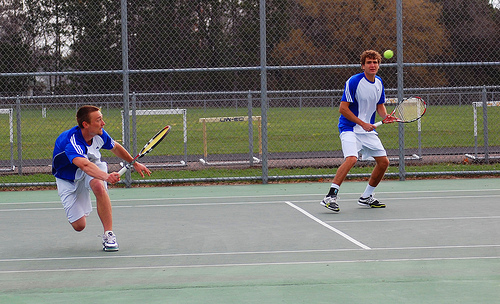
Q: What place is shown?
A: It is a forest.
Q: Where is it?
A: This is at the forest.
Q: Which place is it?
A: It is a forest.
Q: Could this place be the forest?
A: Yes, it is the forest.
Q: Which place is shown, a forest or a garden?
A: It is a forest.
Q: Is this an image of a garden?
A: No, the picture is showing a forest.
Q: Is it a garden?
A: No, it is a forest.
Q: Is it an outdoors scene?
A: Yes, it is outdoors.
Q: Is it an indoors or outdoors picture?
A: It is outdoors.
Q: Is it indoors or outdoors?
A: It is outdoors.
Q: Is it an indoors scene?
A: No, it is outdoors.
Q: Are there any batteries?
A: No, there are no batteries.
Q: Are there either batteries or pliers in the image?
A: No, there are no batteries or pliers.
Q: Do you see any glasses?
A: No, there are no glasses.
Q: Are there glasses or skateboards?
A: No, there are no glasses or skateboards.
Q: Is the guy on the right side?
A: Yes, the guy is on the right of the image.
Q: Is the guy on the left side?
A: No, the guy is on the right of the image.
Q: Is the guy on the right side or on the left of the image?
A: The guy is on the right of the image.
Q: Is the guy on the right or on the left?
A: The guy is on the right of the image.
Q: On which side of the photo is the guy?
A: The guy is on the right of the image.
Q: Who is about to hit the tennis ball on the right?
A: The guy is about to hit the tennis ball.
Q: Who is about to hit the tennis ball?
A: The guy is about to hit the tennis ball.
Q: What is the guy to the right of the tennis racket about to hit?
A: The guy is about to hit the tennis ball.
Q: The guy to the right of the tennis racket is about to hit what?
A: The guy is about to hit the tennis ball.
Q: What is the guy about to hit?
A: The guy is about to hit the tennis ball.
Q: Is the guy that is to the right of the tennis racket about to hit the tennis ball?
A: Yes, the guy is about to hit the tennis ball.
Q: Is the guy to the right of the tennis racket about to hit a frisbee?
A: No, the guy is about to hit the tennis ball.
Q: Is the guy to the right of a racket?
A: Yes, the guy is to the right of a racket.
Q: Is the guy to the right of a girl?
A: No, the guy is to the right of a racket.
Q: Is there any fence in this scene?
A: Yes, there is a fence.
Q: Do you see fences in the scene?
A: Yes, there is a fence.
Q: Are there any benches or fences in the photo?
A: Yes, there is a fence.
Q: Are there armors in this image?
A: No, there are no armors.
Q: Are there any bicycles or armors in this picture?
A: No, there are no armors or bicycles.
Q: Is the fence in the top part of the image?
A: Yes, the fence is in the top of the image.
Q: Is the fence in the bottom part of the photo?
A: No, the fence is in the top of the image.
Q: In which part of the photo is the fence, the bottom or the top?
A: The fence is in the top of the image.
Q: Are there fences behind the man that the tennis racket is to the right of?
A: Yes, there is a fence behind the man.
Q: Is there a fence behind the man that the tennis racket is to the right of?
A: Yes, there is a fence behind the man.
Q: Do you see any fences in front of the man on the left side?
A: No, the fence is behind the man.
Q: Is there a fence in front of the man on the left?
A: No, the fence is behind the man.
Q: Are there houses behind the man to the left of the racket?
A: No, there is a fence behind the man.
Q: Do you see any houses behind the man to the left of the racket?
A: No, there is a fence behind the man.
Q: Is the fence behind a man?
A: Yes, the fence is behind a man.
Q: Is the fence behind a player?
A: No, the fence is behind a man.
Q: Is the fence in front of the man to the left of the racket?
A: No, the fence is behind the man.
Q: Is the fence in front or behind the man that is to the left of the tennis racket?
A: The fence is behind the man.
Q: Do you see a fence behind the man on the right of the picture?
A: Yes, there is a fence behind the man.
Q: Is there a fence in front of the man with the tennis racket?
A: No, the fence is behind the man.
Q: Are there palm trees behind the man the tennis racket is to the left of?
A: No, there is a fence behind the man.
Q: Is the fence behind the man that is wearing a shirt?
A: Yes, the fence is behind the man.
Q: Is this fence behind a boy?
A: No, the fence is behind the man.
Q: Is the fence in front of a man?
A: No, the fence is behind a man.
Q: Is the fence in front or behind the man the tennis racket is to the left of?
A: The fence is behind the man.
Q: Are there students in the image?
A: No, there are no students.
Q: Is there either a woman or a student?
A: No, there are no students or women.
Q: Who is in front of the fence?
A: The man is in front of the fence.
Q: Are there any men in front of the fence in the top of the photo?
A: Yes, there is a man in front of the fence.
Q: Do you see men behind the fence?
A: No, the man is in front of the fence.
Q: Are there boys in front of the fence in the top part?
A: No, there is a man in front of the fence.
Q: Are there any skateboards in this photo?
A: No, there are no skateboards.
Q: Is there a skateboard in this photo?
A: No, there are no skateboards.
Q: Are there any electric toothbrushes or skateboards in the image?
A: No, there are no skateboards or electric toothbrushes.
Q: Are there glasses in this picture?
A: No, there are no glasses.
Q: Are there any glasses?
A: No, there are no glasses.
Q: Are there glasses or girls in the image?
A: No, there are no glasses or girls.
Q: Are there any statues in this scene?
A: No, there are no statues.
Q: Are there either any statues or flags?
A: No, there are no statues or flags.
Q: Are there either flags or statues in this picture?
A: No, there are no statues or flags.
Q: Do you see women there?
A: No, there are no women.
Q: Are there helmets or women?
A: No, there are no women or helmets.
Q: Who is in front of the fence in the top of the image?
A: The man is in front of the fence.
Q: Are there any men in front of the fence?
A: Yes, there is a man in front of the fence.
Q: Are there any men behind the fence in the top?
A: No, the man is in front of the fence.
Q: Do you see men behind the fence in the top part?
A: No, the man is in front of the fence.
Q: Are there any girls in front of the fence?
A: No, there is a man in front of the fence.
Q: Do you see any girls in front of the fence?
A: No, there is a man in front of the fence.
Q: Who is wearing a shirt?
A: The man is wearing a shirt.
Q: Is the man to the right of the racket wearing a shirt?
A: Yes, the man is wearing a shirt.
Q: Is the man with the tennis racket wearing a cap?
A: No, the man is wearing a shirt.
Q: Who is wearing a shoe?
A: The man is wearing a shoe.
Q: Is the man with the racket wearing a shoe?
A: Yes, the man is wearing a shoe.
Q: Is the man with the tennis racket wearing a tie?
A: No, the man is wearing a shoe.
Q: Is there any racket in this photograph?
A: Yes, there is a racket.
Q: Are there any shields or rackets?
A: Yes, there is a racket.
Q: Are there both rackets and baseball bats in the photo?
A: No, there is a racket but no baseball bats.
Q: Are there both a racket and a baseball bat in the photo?
A: No, there is a racket but no baseball bats.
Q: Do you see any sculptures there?
A: No, there are no sculptures.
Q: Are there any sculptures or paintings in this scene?
A: No, there are no sculptures or paintings.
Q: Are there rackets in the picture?
A: Yes, there is a racket.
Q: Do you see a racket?
A: Yes, there is a racket.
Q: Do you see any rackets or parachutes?
A: Yes, there is a racket.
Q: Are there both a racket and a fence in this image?
A: Yes, there are both a racket and a fence.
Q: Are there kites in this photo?
A: No, there are no kites.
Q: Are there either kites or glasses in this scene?
A: No, there are no kites or glasses.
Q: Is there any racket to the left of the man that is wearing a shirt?
A: Yes, there is a racket to the left of the man.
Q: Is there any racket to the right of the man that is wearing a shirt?
A: No, the racket is to the left of the man.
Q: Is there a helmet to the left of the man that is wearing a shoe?
A: No, there is a racket to the left of the man.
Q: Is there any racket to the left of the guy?
A: Yes, there is a racket to the left of the guy.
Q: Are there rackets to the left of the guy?
A: Yes, there is a racket to the left of the guy.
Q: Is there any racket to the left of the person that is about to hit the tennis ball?
A: Yes, there is a racket to the left of the guy.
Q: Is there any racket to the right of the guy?
A: No, the racket is to the left of the guy.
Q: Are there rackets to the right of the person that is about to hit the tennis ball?
A: No, the racket is to the left of the guy.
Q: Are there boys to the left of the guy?
A: No, there is a racket to the left of the guy.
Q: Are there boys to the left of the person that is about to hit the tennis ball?
A: No, there is a racket to the left of the guy.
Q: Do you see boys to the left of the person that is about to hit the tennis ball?
A: No, there is a racket to the left of the guy.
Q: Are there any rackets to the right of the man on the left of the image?
A: Yes, there is a racket to the right of the man.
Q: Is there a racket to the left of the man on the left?
A: No, the racket is to the right of the man.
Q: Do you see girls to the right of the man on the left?
A: No, there is a racket to the right of the man.